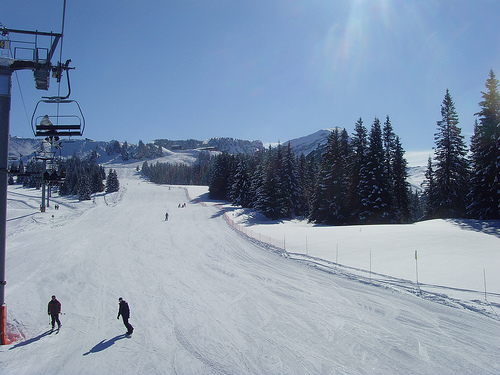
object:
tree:
[308, 126, 353, 226]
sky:
[78, 6, 181, 50]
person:
[115, 297, 134, 339]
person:
[164, 210, 170, 223]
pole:
[481, 266, 489, 304]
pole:
[412, 249, 421, 286]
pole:
[367, 245, 374, 277]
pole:
[332, 239, 344, 270]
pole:
[304, 232, 308, 256]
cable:
[49, 5, 67, 159]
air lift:
[30, 96, 87, 137]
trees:
[59, 152, 119, 201]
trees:
[113, 138, 164, 160]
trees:
[203, 136, 260, 152]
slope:
[149, 223, 387, 348]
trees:
[283, 141, 305, 216]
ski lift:
[31, 62, 83, 137]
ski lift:
[36, 155, 66, 185]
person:
[40, 114, 62, 142]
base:
[1, 301, 6, 347]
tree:
[466, 68, 500, 222]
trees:
[359, 115, 398, 225]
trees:
[314, 125, 360, 224]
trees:
[254, 146, 290, 221]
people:
[44, 295, 63, 330]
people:
[116, 297, 134, 335]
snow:
[412, 232, 497, 275]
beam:
[0, 58, 19, 338]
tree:
[410, 83, 472, 220]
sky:
[373, 0, 498, 40]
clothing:
[118, 301, 132, 333]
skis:
[49, 323, 60, 333]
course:
[0, 57, 499, 372]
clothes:
[48, 299, 62, 327]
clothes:
[165, 214, 169, 220]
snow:
[93, 267, 163, 299]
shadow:
[82, 330, 125, 354]